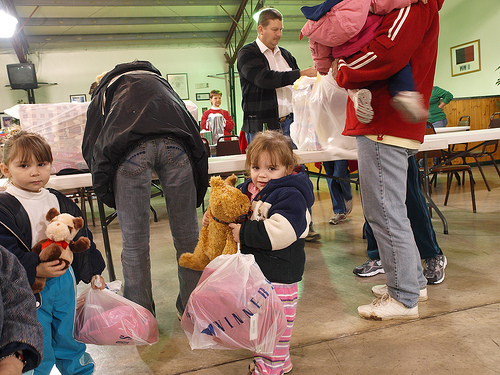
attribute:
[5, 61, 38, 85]
tv — old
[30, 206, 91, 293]
bear — brown, white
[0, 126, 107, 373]
girl — little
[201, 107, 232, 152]
shirt — white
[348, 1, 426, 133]
jacket — red, white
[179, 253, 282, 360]
bag — white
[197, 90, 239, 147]
woman — brunette, white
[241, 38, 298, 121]
sweater — black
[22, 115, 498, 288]
table — white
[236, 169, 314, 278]
coat — black, white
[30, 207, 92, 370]
stuffed animal — tan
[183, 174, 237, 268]
stuffed animal — tan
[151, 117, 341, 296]
child — white 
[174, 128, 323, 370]
girl — little